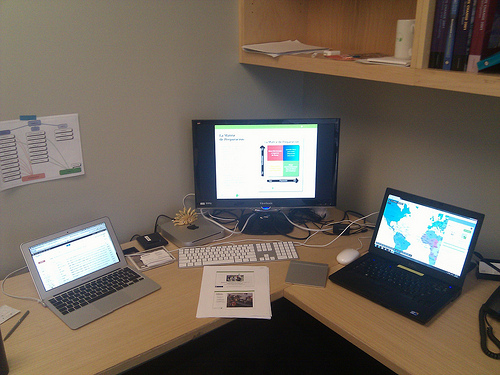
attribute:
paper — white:
[196, 262, 277, 320]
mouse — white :
[335, 240, 367, 269]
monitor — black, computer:
[183, 112, 343, 209]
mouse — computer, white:
[337, 243, 360, 264]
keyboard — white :
[173, 237, 296, 264]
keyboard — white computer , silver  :
[177, 239, 301, 267]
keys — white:
[180, 249, 281, 265]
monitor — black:
[182, 106, 399, 232]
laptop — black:
[335, 182, 482, 332]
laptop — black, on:
[327, 187, 484, 325]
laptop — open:
[279, 175, 497, 367]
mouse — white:
[337, 249, 359, 266]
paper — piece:
[195, 261, 271, 323]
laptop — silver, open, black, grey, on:
[18, 215, 162, 330]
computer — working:
[190, 117, 344, 237]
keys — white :
[176, 241, 291, 265]